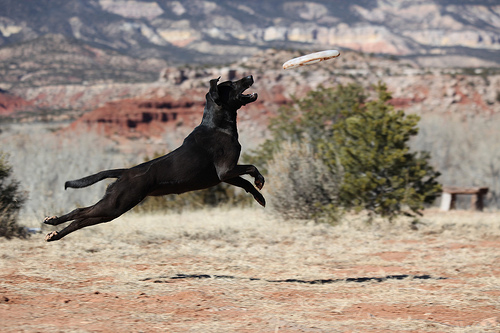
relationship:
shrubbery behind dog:
[127, 71, 440, 231] [42, 73, 267, 240]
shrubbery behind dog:
[1, 151, 41, 241] [42, 73, 267, 240]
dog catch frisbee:
[41, 74, 266, 242] [271, 44, 355, 78]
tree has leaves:
[297, 106, 434, 214] [388, 154, 417, 180]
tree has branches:
[297, 106, 434, 214] [370, 83, 420, 157]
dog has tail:
[41, 74, 266, 242] [62, 164, 130, 191]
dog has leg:
[42, 73, 267, 240] [46, 192, 136, 242]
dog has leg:
[42, 73, 267, 240] [42, 195, 103, 224]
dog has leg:
[42, 73, 267, 240] [232, 164, 265, 189]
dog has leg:
[42, 73, 267, 240] [220, 172, 267, 205]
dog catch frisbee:
[42, 73, 267, 240] [283, 50, 340, 70]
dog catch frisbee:
[42, 73, 267, 240] [283, 45, 340, 70]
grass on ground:
[280, 89, 458, 213] [0, 198, 492, 328]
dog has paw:
[42, 73, 267, 240] [46, 229, 58, 240]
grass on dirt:
[0, 208, 350, 259] [3, 265, 498, 331]